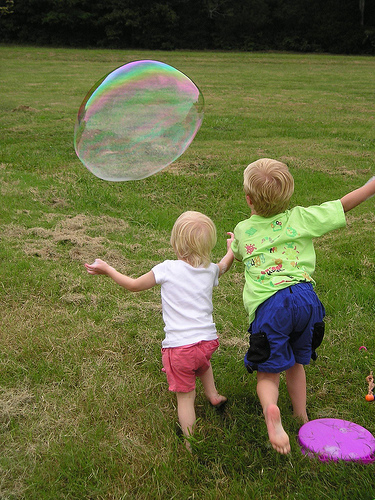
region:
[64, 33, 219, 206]
giant bubble floating in air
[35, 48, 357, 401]
children running after bubble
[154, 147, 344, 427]
two blond children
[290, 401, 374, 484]
purple frisbee on grass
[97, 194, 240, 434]
young child in white shirt and red shorts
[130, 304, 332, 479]
children playing barefoot in the grass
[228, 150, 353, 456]
young boy in green t-shirt and blue shorts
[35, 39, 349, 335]
children chasing giant bubble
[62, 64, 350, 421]
children playing at the park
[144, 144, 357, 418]
two brothers in the park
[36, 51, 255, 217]
a big bubble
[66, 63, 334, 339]
two children playing bubbles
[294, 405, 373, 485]
a purple frisbee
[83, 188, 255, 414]
a small child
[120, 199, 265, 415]
a small child wearing pink shorts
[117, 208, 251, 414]
a small child wearing a white shirt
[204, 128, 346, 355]
a small child wearing blue shorts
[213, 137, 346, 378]
a small child wearing a green shirt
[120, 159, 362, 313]
two blonde children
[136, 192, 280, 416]
a small child with blonde hair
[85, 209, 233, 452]
Girl wearing pink shorts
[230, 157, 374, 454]
Boy wearing blue pants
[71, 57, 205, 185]
Huge bubble above children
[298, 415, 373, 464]
Pink frisbee behind boy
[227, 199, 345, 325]
Shirt is green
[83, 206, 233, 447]
Girl running after clear bubble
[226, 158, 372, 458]
Boy running after big bubble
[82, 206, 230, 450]
Girl is barefoot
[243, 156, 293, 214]
Hair is blonde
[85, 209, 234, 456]
Girl has arms extended out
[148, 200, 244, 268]
little girls blonde hair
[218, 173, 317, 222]
little boy blond hair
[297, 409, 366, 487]
pruple Frisbee on ground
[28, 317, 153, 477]
some green grass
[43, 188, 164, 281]
some burnt grass on ground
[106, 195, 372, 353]
brother and sister playing with bubbles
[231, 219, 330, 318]
the older boys green shirt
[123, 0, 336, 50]
trees in the background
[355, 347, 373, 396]
something orange in the ground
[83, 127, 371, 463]
children playing in a field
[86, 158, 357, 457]
children running in the grass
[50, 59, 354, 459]
two young children chase a bubble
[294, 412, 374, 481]
a purple toy lying in the grass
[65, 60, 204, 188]
a large bubble floating in the air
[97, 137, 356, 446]
two young children running towards a big bubble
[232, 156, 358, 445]
the older boy wears blue shorts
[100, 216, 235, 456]
the smaller child is wearing red shorts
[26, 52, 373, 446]
the grass is green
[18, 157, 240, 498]
there are lawn clippings on the ground